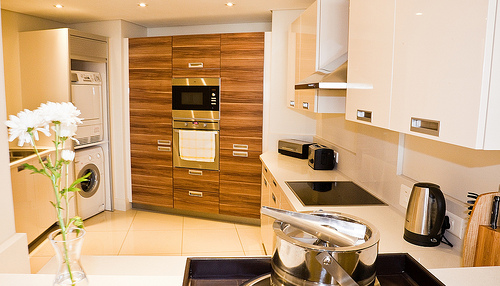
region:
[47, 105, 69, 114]
white petals of a flower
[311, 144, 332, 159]
a bread toaster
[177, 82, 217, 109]
an oven mounted on the wall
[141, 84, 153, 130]
wooden wall holding the oven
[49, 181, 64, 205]
the stalk of a flower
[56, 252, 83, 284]
a flower vessel in a room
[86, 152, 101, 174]
the dry clean machine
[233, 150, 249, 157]
the handle of a wooden door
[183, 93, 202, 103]
the glass window of an oven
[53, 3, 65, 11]
a light bulb on the ceiling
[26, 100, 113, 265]
this is a flower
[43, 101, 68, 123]
the flower is white in color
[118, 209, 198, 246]
this is the floor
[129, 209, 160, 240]
the floor is brown in color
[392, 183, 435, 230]
this is a kettle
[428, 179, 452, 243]
the handle is black in color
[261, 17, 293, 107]
this is the wall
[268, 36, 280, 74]
the wall is white in color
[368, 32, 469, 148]
this is a cupboard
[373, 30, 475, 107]
the cupboard is white in color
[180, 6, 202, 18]
this is the ceiling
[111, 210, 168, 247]
this is the floor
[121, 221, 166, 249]
the floor has tiles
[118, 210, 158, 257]
the tiles are white in color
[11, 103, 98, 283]
these are some flowers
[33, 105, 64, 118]
the flowers are white in color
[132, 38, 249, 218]
these are some drawers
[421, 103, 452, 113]
the cupboard is white in color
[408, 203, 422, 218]
the kettle is metallic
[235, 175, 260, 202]
the area is brown in color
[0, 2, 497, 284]
interior of modern kitchen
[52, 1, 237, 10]
three glowing recessed lights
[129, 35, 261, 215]
oven in wood wall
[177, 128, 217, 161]
towel hanging from handle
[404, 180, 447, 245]
pot with black handle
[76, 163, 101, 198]
round window of washer machine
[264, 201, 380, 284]
tongs on ice bucket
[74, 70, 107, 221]
two stacked white appliances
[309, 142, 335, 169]
black and silver toaster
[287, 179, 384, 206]
shiny black surface on counter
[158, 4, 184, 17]
this is the ceiling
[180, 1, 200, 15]
the ceiling is white in color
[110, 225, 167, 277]
this is the floor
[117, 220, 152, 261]
the floor has tiles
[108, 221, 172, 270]
the tiles are white in color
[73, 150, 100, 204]
this is a washing machine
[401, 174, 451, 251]
this is a kettle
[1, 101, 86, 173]
this is a flower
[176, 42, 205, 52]
the area is brown in color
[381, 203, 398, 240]
the table is clean